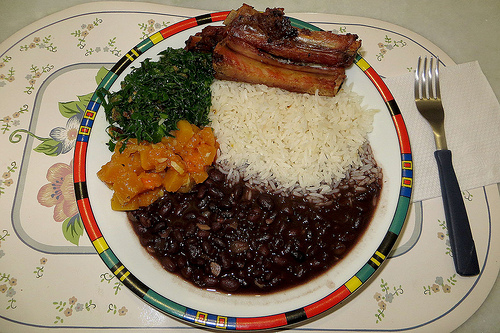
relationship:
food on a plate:
[97, 4, 390, 299] [70, 6, 417, 331]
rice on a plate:
[209, 79, 383, 205] [70, 6, 417, 331]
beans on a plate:
[126, 169, 382, 296] [70, 6, 417, 331]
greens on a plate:
[98, 48, 222, 144] [70, 6, 417, 331]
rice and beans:
[209, 79, 383, 205] [114, 169, 382, 296]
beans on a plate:
[114, 169, 382, 296] [70, 6, 417, 331]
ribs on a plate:
[211, 7, 382, 85] [135, 263, 399, 323]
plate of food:
[70, 6, 417, 331] [181, 1, 361, 95]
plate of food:
[70, 6, 417, 331] [96, 45, 213, 153]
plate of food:
[70, 6, 417, 331] [96, 119, 218, 211]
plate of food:
[70, 6, 417, 331] [205, 79, 382, 203]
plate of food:
[70, 6, 417, 331] [125, 166, 382, 295]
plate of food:
[70, 6, 417, 331] [97, 4, 390, 299]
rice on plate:
[209, 79, 383, 205] [70, 6, 417, 331]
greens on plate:
[98, 48, 222, 144] [70, 6, 417, 331]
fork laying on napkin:
[413, 56, 480, 277] [444, 55, 498, 192]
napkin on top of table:
[385, 60, 499, 199] [420, 12, 460, 49]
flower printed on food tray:
[36, 163, 79, 223] [0, 0, 500, 332]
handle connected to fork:
[435, 147, 481, 282] [413, 50, 480, 277]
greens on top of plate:
[98, 48, 222, 144] [74, 123, 129, 287]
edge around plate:
[72, 118, 100, 235] [70, 6, 417, 331]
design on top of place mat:
[27, 69, 72, 250] [0, 6, 79, 328]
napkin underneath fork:
[385, 60, 499, 199] [413, 50, 480, 277]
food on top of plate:
[97, 4, 390, 299] [70, 6, 417, 331]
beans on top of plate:
[114, 169, 382, 296] [70, 6, 417, 331]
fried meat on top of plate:
[222, 2, 361, 66] [70, 6, 417, 331]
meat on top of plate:
[210, 37, 341, 96] [70, 6, 417, 331]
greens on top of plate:
[113, 69, 213, 144] [315, 72, 439, 233]